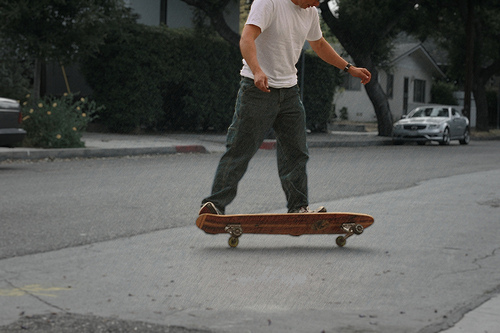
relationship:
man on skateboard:
[198, 1, 373, 216] [194, 212, 375, 246]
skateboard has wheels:
[194, 212, 375, 246] [224, 223, 243, 249]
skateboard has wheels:
[194, 212, 375, 246] [335, 222, 366, 248]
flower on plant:
[79, 97, 85, 104] [14, 87, 106, 151]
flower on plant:
[79, 110, 87, 118] [14, 87, 106, 151]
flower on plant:
[55, 134, 63, 140] [14, 87, 106, 151]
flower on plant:
[44, 109, 51, 117] [14, 87, 106, 151]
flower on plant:
[36, 102, 45, 108] [14, 87, 106, 151]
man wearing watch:
[198, 1, 373, 216] [341, 61, 355, 76]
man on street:
[198, 1, 373, 216] [0, 138, 498, 331]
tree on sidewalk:
[320, 0, 410, 135] [2, 128, 389, 163]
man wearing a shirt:
[198, 1, 373, 216] [237, 0, 325, 89]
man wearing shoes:
[198, 1, 373, 216] [196, 201, 327, 214]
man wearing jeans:
[198, 1, 373, 216] [199, 76, 310, 211]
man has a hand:
[198, 1, 373, 216] [251, 71, 276, 93]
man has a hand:
[198, 1, 373, 216] [351, 64, 372, 84]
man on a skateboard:
[198, 1, 373, 216] [194, 212, 375, 246]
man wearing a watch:
[198, 1, 373, 216] [341, 61, 355, 76]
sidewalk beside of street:
[2, 128, 389, 163] [0, 138, 498, 331]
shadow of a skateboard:
[196, 244, 377, 254] [194, 212, 375, 246]